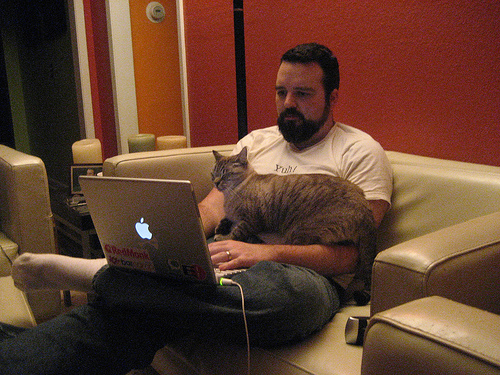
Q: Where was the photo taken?
A: Living room.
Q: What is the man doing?
A: Using a computer.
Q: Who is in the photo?
A: A man.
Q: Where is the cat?
A: Sitting on the man's lap.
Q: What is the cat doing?
A: Looking at the computer.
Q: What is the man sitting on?
A: A chair.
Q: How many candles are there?
A: Three.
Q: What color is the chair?
A: Tan.